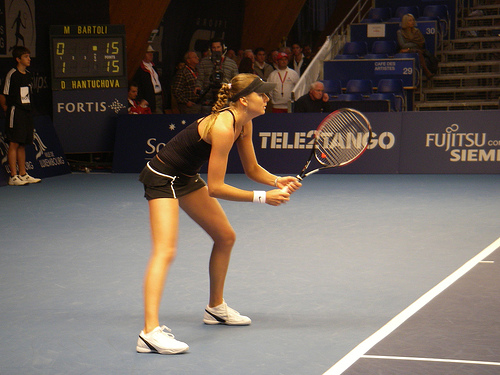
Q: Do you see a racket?
A: Yes, there is a racket.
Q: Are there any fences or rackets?
A: Yes, there is a racket.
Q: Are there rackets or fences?
A: Yes, there is a racket.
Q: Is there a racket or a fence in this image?
A: Yes, there is a racket.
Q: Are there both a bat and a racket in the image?
A: No, there is a racket but no bats.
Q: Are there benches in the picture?
A: No, there are no benches.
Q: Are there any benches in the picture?
A: No, there are no benches.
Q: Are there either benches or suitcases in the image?
A: No, there are no benches or suitcases.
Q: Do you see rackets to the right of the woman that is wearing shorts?
A: Yes, there is a racket to the right of the woman.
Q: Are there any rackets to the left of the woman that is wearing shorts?
A: No, the racket is to the right of the woman.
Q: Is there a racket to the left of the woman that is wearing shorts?
A: No, the racket is to the right of the woman.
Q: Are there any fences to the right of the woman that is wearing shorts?
A: No, there is a racket to the right of the woman.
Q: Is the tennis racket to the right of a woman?
A: Yes, the tennis racket is to the right of a woman.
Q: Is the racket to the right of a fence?
A: No, the racket is to the right of a woman.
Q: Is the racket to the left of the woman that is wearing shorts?
A: No, the racket is to the right of the woman.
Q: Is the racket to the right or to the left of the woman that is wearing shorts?
A: The racket is to the right of the woman.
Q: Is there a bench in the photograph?
A: No, there are no benches.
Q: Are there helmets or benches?
A: No, there are no benches or helmets.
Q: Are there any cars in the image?
A: No, there are no cars.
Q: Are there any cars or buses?
A: No, there are no cars or buses.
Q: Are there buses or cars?
A: No, there are no cars or buses.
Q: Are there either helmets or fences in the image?
A: No, there are no fences or helmets.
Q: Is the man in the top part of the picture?
A: Yes, the man is in the top of the image.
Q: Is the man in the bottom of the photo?
A: No, the man is in the top of the image.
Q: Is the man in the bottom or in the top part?
A: The man is in the top of the image.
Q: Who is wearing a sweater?
A: The man is wearing a sweater.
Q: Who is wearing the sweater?
A: The man is wearing a sweater.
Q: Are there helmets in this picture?
A: No, there are no helmets.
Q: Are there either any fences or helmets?
A: No, there are no helmets or fences.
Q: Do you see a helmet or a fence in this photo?
A: No, there are no helmets or fences.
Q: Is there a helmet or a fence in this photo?
A: No, there are no helmets or fences.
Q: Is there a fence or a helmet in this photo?
A: No, there are no helmets or fences.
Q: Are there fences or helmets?
A: No, there are no helmets or fences.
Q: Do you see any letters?
A: Yes, there are letters.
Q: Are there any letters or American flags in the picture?
A: Yes, there are letters.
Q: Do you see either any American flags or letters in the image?
A: Yes, there are letters.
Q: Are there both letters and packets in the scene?
A: No, there are letters but no packets.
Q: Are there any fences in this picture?
A: No, there are no fences.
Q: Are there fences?
A: No, there are no fences.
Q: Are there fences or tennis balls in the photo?
A: No, there are no fences or tennis balls.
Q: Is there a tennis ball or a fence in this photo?
A: No, there are no fences or tennis balls.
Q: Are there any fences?
A: No, there are no fences.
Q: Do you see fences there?
A: No, there are no fences.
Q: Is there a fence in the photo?
A: No, there are no fences.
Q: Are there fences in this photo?
A: No, there are no fences.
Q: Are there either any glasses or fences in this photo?
A: No, there are no fences or glasses.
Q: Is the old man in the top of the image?
A: Yes, the man is in the top of the image.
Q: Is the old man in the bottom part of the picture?
A: No, the man is in the top of the image.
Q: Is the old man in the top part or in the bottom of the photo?
A: The man is in the top of the image.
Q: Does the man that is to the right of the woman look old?
A: Yes, the man is old.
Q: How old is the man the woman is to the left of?
A: The man is old.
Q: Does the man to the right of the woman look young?
A: No, the man is old.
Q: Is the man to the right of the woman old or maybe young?
A: The man is old.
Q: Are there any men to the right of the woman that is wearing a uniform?
A: Yes, there is a man to the right of the woman.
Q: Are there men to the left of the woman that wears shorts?
A: No, the man is to the right of the woman.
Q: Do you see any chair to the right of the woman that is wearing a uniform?
A: No, there is a man to the right of the woman.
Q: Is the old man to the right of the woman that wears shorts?
A: Yes, the man is to the right of the woman.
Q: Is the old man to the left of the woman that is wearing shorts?
A: No, the man is to the right of the woman.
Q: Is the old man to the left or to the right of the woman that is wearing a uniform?
A: The man is to the right of the woman.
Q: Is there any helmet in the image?
A: No, there are no helmets.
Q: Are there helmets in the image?
A: No, there are no helmets.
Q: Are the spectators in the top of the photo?
A: Yes, the spectators are in the top of the image.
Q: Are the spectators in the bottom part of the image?
A: No, the spectators are in the top of the image.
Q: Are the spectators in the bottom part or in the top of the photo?
A: The spectators are in the top of the image.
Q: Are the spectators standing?
A: Yes, the spectators are standing.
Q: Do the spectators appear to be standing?
A: Yes, the spectators are standing.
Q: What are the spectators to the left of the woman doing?
A: The spectators are standing.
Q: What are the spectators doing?
A: The spectators are standing.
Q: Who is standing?
A: The spectators are standing.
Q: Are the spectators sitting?
A: No, the spectators are standing.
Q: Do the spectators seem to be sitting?
A: No, the spectators are standing.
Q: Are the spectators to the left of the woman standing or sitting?
A: The spectators are standing.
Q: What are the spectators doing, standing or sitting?
A: The spectators are standing.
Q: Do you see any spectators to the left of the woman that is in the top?
A: Yes, there are spectators to the left of the woman.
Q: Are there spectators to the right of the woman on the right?
A: No, the spectators are to the left of the woman.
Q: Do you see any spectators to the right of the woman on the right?
A: No, the spectators are to the left of the woman.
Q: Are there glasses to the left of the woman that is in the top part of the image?
A: No, there are spectators to the left of the woman.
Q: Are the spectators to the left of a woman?
A: Yes, the spectators are to the left of a woman.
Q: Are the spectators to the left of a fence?
A: No, the spectators are to the left of a woman.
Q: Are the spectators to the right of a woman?
A: No, the spectators are to the left of a woman.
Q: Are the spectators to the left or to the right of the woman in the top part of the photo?
A: The spectators are to the left of the woman.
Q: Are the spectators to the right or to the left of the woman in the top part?
A: The spectators are to the left of the woman.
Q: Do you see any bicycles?
A: No, there are no bicycles.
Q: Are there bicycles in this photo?
A: No, there are no bicycles.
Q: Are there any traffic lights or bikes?
A: No, there are no bikes or traffic lights.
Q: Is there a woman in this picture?
A: Yes, there is a woman.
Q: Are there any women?
A: Yes, there is a woman.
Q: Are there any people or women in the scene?
A: Yes, there is a woman.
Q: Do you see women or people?
A: Yes, there is a woman.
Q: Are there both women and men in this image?
A: Yes, there are both a woman and a man.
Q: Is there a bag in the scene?
A: No, there are no bags.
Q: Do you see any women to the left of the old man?
A: Yes, there is a woman to the left of the man.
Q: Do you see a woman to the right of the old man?
A: No, the woman is to the left of the man.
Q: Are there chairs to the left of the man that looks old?
A: No, there is a woman to the left of the man.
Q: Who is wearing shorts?
A: The woman is wearing shorts.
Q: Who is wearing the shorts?
A: The woman is wearing shorts.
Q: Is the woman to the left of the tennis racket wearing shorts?
A: Yes, the woman is wearing shorts.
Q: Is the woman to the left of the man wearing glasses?
A: No, the woman is wearing shorts.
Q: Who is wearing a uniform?
A: The woman is wearing a uniform.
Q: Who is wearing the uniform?
A: The woman is wearing a uniform.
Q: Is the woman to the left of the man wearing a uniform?
A: Yes, the woman is wearing a uniform.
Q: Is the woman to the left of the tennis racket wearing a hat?
A: No, the woman is wearing a uniform.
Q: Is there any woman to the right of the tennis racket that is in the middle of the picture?
A: No, the woman is to the left of the tennis racket.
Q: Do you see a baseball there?
A: No, there are no baseballs.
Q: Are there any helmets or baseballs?
A: No, there are no baseballs or helmets.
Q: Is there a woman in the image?
A: Yes, there is a woman.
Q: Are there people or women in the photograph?
A: Yes, there is a woman.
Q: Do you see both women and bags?
A: No, there is a woman but no bags.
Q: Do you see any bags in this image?
A: No, there are no bags.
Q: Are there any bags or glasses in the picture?
A: No, there are no bags or glasses.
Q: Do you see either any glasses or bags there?
A: No, there are no bags or glasses.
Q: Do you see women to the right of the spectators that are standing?
A: Yes, there is a woman to the right of the spectators.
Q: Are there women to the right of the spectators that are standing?
A: Yes, there is a woman to the right of the spectators.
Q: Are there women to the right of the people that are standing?
A: Yes, there is a woman to the right of the spectators.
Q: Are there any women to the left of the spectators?
A: No, the woman is to the right of the spectators.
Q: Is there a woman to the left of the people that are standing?
A: No, the woman is to the right of the spectators.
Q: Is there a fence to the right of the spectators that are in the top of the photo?
A: No, there is a woman to the right of the spectators.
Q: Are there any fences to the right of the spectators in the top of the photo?
A: No, there is a woman to the right of the spectators.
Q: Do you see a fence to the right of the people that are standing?
A: No, there is a woman to the right of the spectators.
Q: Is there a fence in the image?
A: No, there are no fences.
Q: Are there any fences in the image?
A: No, there are no fences.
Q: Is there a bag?
A: No, there are no bags.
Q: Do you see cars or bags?
A: No, there are no bags or cars.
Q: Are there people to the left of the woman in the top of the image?
A: Yes, there are people to the left of the woman.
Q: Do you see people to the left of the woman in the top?
A: Yes, there are people to the left of the woman.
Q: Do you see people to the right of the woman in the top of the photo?
A: No, the people are to the left of the woman.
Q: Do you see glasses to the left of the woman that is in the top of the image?
A: No, there are people to the left of the woman.